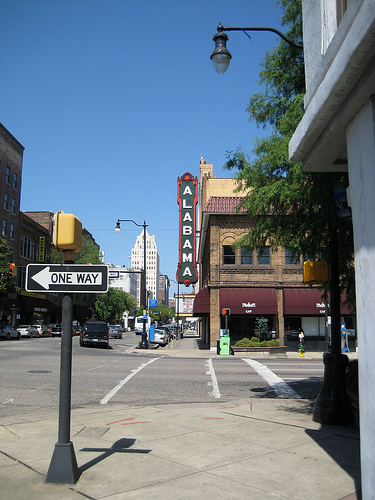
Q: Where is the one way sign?
A: Side of crosswalk.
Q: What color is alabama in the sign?
A: White.